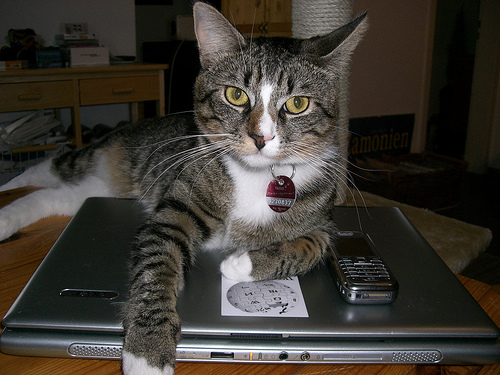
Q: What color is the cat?
A: Gray and white.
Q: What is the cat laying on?
A: A laptop.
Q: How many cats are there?
A: 1.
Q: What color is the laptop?
A: Gray.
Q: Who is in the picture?
A: A cat.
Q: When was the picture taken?
A: When the cat was on the laptop.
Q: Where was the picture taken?
A: On a table.